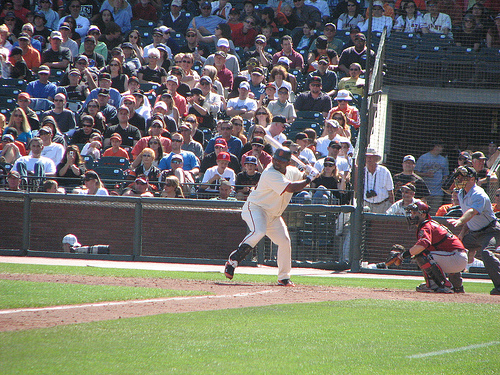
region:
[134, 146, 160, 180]
a baseball sitting in the stand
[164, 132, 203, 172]
a baseball sitting in the stand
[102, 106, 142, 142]
a baseball sitting in the stand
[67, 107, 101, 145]
a baseball sitting in the stand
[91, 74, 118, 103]
a baseball sitting in the stand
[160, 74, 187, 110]
a baseball sitting in the stand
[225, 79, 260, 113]
a baseball sitting in the stand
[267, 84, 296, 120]
a baseball sitting in the stand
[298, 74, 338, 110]
a baseball sitting in the stand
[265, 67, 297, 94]
a baseball sitting in the stand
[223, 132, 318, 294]
Batter ready to swing.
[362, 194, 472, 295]
Catcher, crouched to catch the ball.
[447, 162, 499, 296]
Umpire.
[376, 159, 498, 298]
An umpire standing behind the catcher.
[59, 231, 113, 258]
A photographer with a zoom lens on his camera.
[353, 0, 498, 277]
Netting behind home plate to protect bystanders.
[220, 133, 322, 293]
Batter in a white uniform.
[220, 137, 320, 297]
Batter holding one foot in the air.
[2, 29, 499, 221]
Spectators watching the game.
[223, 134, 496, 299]
Batter, catcher and umpire behind home plate.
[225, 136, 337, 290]
batter at a baseball game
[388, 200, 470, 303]
catcher at a baseball game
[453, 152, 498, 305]
umpire at a baseball game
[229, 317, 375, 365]
green grass of a baseball field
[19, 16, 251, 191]
spectators in the bleachers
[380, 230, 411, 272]
matt of a catcher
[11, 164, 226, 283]
fence on side of field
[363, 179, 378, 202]
camera on man's neck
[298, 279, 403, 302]
dirt ground of a baseball field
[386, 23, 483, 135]
net in front of the spectators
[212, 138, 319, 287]
Player hitting the ball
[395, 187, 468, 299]
Catcher catching the ball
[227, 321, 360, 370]
Green infield of field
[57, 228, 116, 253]
Photographer zooming in on player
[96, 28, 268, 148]
Fans watching the game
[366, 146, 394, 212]
Man with a hat and camera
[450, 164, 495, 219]
Umpire behind the catcher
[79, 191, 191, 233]
Green metal fence on field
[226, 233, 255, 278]
Shin guard on player's leg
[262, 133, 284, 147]
Tip of bat in the air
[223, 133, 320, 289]
batter coiled to swing his bat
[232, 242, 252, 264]
pad to absorb impact of foul balls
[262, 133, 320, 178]
bat in the swinging position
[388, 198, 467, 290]
catcher crouching to receive the pitch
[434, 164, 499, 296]
umpire ready to make the call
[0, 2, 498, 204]
spectators watching the game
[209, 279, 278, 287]
shadow of the batter on the ground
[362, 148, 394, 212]
man with a camera around his neck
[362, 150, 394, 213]
man wearing a hat with a brim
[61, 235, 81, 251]
ball cap of the camera man